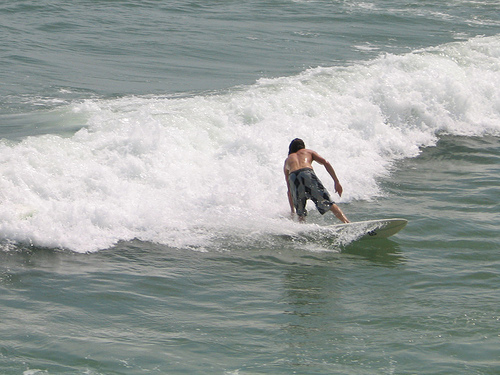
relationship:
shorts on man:
[287, 170, 333, 217] [281, 135, 348, 232]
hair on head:
[291, 141, 306, 144] [287, 138, 304, 157]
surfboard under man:
[337, 215, 410, 238] [281, 135, 348, 232]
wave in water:
[30, 108, 192, 215] [20, 8, 378, 59]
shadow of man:
[343, 244, 407, 274] [281, 135, 348, 232]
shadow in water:
[343, 244, 407, 274] [20, 8, 378, 59]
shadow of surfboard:
[343, 244, 407, 274] [337, 215, 410, 238]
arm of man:
[313, 155, 349, 201] [281, 135, 348, 232]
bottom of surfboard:
[333, 232, 402, 239] [337, 215, 410, 238]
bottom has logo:
[333, 232, 402, 239] [367, 229, 377, 237]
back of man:
[289, 153, 308, 170] [281, 135, 348, 232]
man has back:
[281, 135, 348, 232] [289, 153, 308, 170]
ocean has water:
[11, 7, 489, 132] [20, 8, 378, 59]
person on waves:
[281, 135, 348, 232] [11, 53, 485, 122]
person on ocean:
[281, 135, 348, 232] [11, 7, 489, 132]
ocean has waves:
[11, 7, 489, 132] [11, 53, 485, 122]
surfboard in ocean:
[337, 215, 410, 238] [11, 7, 489, 132]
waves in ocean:
[11, 53, 485, 122] [11, 7, 489, 132]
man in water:
[281, 135, 348, 232] [20, 8, 378, 59]